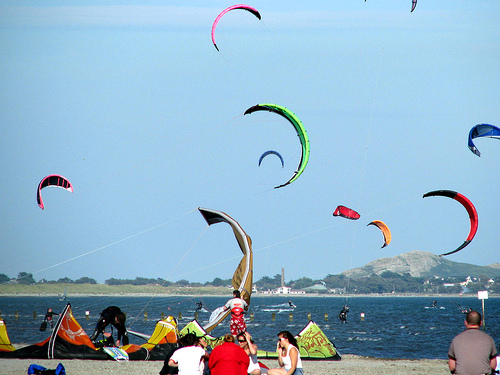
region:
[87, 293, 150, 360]
the man is wearing wetsuit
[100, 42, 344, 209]
the sky is clear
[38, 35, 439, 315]
kites on the air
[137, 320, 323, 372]
the people are sitting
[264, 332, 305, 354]
woman is wearing sunglasses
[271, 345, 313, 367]
the shirt is white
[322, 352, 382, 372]
the sand is gray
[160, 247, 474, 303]
mountain in the distance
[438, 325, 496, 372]
the shirt is brown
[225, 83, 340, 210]
the kite is green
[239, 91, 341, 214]
a green wind sail.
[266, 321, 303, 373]
a woman in a white tank top.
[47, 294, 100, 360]
a red sail at a beach.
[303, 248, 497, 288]
a large hill near a body of water.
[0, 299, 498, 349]
a large body of water.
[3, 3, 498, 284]
a light blue sky filled with kites.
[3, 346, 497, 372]
a sandy beach with people standing on it.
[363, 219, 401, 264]
an orange kite.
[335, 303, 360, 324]
a person kite boarding.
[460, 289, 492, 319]
a white sign at a beach.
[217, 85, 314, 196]
A green kite in the air.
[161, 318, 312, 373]
People sitting on the beach.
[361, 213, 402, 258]
An orange kite in the air.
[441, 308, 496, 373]
The man is wearing a gray shirt.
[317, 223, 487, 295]
A hill in the distance.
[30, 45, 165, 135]
The sky is blue.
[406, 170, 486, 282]
A red and black kite.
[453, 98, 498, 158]
A blue kite in the air.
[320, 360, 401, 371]
Sand on the beach.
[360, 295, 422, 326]
The water is blue.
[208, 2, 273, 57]
Pink kite flying in sky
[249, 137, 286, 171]
Blue kite flying in sky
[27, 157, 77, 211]
Blue and pink kite flying in sky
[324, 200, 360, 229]
Red kite flying in sky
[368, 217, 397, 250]
Orange kite flying in sky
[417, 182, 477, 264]
Red and black kite flying in sky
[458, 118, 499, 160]
Blue kite flying in sky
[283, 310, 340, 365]
Green kite laying on beach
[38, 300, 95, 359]
Orange kite laying on beach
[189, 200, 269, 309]
Man trying to launch brown kite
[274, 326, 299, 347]
the head of a woman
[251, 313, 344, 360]
a green kite on the ground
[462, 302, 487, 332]
the head of a man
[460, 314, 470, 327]
the ear of a man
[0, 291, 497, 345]
a blue body of water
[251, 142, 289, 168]
a blue kite in the sky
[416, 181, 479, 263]
a red and black kite in the sky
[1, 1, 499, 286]
a clear blue sky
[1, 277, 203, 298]
a patch of green grass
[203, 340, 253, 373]
a red shirt